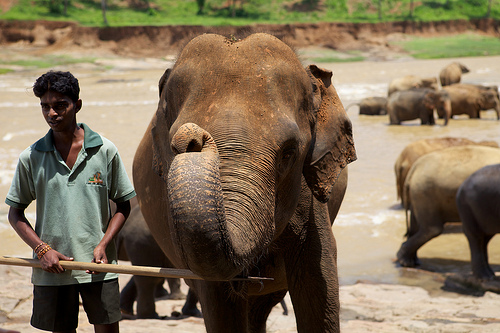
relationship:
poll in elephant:
[69, 259, 187, 281] [150, 132, 325, 249]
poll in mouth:
[69, 259, 187, 281] [219, 243, 292, 297]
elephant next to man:
[118, 30, 361, 332] [6, 70, 136, 331]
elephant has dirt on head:
[118, 35, 354, 332] [158, 31, 346, 281]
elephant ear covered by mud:
[300, 58, 359, 208] [312, 171, 354, 211]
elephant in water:
[118, 30, 361, 332] [347, 214, 405, 293]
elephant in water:
[391, 89, 455, 119] [347, 214, 405, 293]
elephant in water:
[446, 83, 498, 115] [347, 214, 405, 293]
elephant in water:
[437, 62, 469, 85] [1, 56, 498, 331]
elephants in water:
[352, 59, 498, 125] [7, 58, 497, 290]